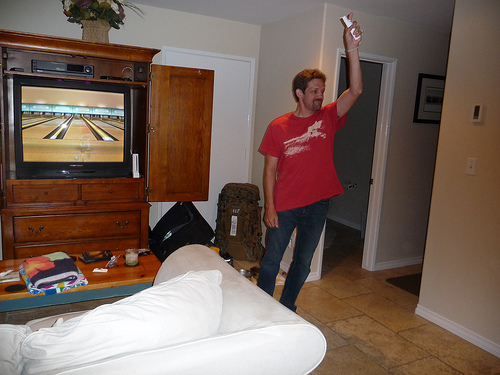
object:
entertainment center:
[9, 79, 141, 179]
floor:
[325, 311, 433, 370]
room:
[1, 0, 500, 375]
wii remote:
[338, 13, 363, 44]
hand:
[343, 10, 363, 49]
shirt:
[257, 99, 349, 212]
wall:
[460, 18, 496, 68]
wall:
[261, 21, 308, 67]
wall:
[458, 288, 500, 324]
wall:
[390, 132, 428, 189]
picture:
[413, 73, 447, 125]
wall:
[436, 180, 494, 223]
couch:
[0, 242, 328, 374]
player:
[30, 57, 95, 78]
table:
[0, 247, 165, 312]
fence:
[4, 74, 140, 181]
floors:
[322, 313, 433, 371]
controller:
[339, 15, 360, 39]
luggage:
[213, 181, 270, 263]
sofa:
[0, 240, 329, 374]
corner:
[402, 280, 434, 321]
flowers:
[60, 0, 135, 42]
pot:
[70, 16, 117, 44]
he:
[256, 12, 366, 313]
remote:
[341, 15, 364, 40]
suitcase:
[213, 182, 271, 263]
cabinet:
[2, 27, 212, 260]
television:
[10, 76, 141, 180]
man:
[256, 11, 365, 314]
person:
[255, 12, 364, 312]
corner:
[222, 10, 295, 46]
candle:
[121, 247, 141, 268]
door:
[319, 46, 398, 279]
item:
[212, 182, 265, 262]